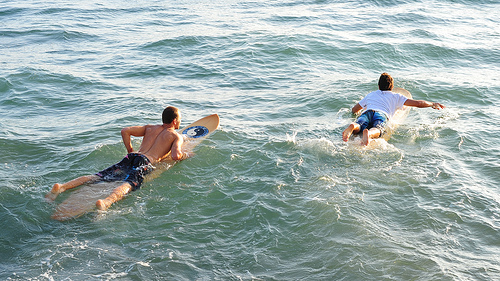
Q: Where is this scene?
A: Ocean.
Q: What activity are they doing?
A: Surfing.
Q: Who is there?
A: 2 surfers.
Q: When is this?
A: During the day.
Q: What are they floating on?
A: Surfboards.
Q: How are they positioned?
A: Laying down.